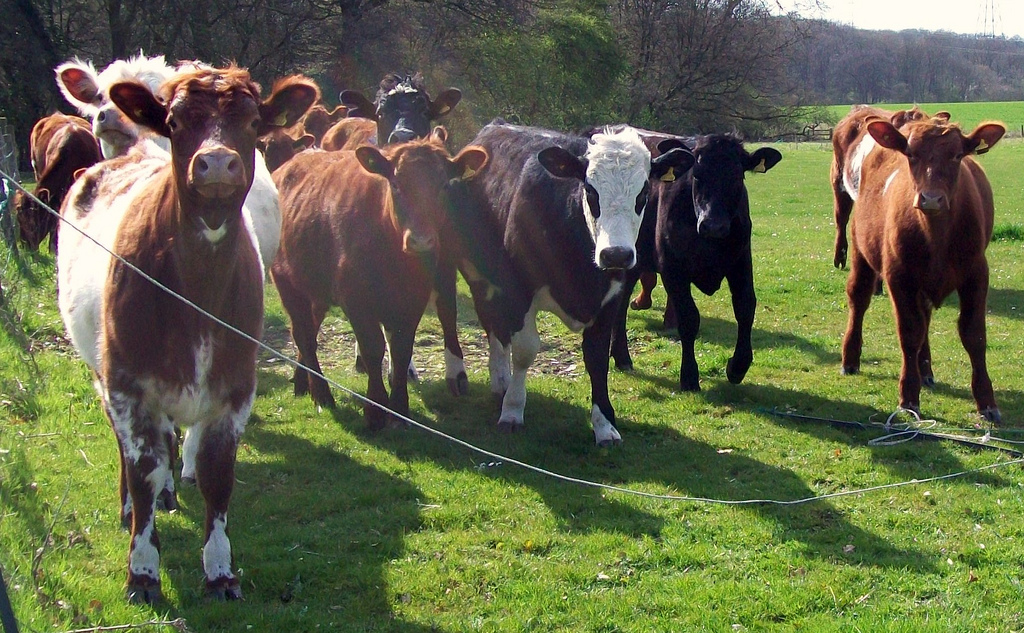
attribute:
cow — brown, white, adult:
[51, 64, 319, 603]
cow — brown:
[833, 112, 1011, 435]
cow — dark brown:
[267, 130, 497, 431]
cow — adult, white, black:
[457, 116, 689, 452]